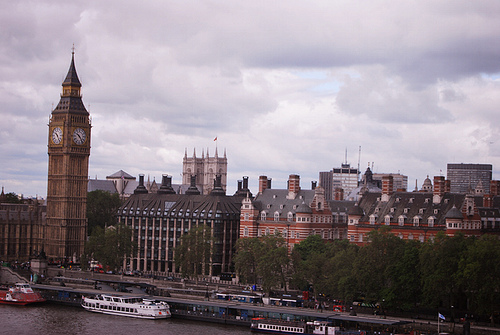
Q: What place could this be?
A: It is a city.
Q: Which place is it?
A: It is a city.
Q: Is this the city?
A: Yes, it is the city.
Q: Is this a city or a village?
A: It is a city.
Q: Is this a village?
A: No, it is a city.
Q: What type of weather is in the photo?
A: It is cloudy.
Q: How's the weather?
A: It is cloudy.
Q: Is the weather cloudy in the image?
A: Yes, it is cloudy.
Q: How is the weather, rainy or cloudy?
A: It is cloudy.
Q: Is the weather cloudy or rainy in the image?
A: It is cloudy.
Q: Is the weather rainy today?
A: No, it is cloudy.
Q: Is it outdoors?
A: Yes, it is outdoors.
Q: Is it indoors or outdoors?
A: It is outdoors.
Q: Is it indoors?
A: No, it is outdoors.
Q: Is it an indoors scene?
A: No, it is outdoors.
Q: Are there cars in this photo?
A: No, there are no cars.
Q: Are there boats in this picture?
A: Yes, there is a boat.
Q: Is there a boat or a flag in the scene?
A: Yes, there is a boat.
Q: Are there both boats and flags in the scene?
A: Yes, there are both a boat and a flag.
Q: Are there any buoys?
A: No, there are no buoys.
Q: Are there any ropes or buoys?
A: No, there are no buoys or ropes.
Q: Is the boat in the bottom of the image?
A: Yes, the boat is in the bottom of the image.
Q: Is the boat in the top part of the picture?
A: No, the boat is in the bottom of the image.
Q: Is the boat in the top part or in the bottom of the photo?
A: The boat is in the bottom of the image.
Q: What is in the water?
A: The boat is in the water.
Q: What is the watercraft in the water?
A: The watercraft is a boat.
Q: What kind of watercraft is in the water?
A: The watercraft is a boat.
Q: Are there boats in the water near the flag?
A: Yes, there is a boat in the water.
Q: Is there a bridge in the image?
A: Yes, there is a bridge.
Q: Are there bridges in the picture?
A: Yes, there is a bridge.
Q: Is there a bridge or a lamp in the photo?
A: Yes, there is a bridge.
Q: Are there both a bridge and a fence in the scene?
A: No, there is a bridge but no fences.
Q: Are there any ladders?
A: No, there are no ladders.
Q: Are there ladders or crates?
A: No, there are no ladders or crates.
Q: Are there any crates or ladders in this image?
A: No, there are no ladders or crates.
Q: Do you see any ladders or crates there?
A: No, there are no ladders or crates.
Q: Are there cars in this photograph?
A: No, there are no cars.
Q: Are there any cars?
A: No, there are no cars.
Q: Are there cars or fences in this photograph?
A: No, there are no cars or fences.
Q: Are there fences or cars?
A: No, there are no cars or fences.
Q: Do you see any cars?
A: No, there are no cars.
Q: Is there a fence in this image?
A: No, there are no fences.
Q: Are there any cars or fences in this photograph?
A: No, there are no fences or cars.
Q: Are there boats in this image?
A: Yes, there is a boat.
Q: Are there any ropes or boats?
A: Yes, there is a boat.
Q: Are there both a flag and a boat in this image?
A: Yes, there are both a boat and a flag.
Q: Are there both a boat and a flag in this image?
A: Yes, there are both a boat and a flag.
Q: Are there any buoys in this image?
A: No, there are no buoys.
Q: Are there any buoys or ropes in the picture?
A: No, there are no buoys or ropes.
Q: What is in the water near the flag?
A: The boat is in the water.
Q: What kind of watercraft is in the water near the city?
A: The watercraft is a boat.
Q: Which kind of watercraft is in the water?
A: The watercraft is a boat.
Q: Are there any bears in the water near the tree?
A: No, there is a boat in the water.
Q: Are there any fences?
A: No, there are no fences.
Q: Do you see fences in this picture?
A: No, there are no fences.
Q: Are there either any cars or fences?
A: No, there are no fences or cars.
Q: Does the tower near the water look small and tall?
A: No, the tower is tall but large.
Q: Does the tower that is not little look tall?
A: Yes, the tower is tall.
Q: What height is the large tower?
A: The tower is tall.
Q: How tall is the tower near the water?
A: The tower is tall.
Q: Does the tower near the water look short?
A: No, the tower is tall.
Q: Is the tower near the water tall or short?
A: The tower is tall.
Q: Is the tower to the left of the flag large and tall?
A: Yes, the tower is large and tall.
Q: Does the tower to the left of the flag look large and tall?
A: Yes, the tower is large and tall.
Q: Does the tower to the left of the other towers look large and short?
A: No, the tower is large but tall.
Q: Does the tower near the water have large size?
A: Yes, the tower is large.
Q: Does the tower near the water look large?
A: Yes, the tower is large.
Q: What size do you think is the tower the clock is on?
A: The tower is large.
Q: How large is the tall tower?
A: The tower is large.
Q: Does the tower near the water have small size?
A: No, the tower is large.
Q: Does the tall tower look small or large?
A: The tower is large.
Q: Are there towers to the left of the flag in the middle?
A: Yes, there is a tower to the left of the flag.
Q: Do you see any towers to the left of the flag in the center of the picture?
A: Yes, there is a tower to the left of the flag.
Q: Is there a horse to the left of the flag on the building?
A: No, there is a tower to the left of the flag.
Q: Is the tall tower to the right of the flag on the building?
A: No, the tower is to the left of the flag.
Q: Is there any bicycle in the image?
A: No, there are no bicycles.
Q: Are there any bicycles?
A: No, there are no bicycles.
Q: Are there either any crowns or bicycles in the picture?
A: No, there are no bicycles or crowns.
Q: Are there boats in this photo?
A: Yes, there is a boat.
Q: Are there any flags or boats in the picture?
A: Yes, there is a boat.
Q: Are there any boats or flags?
A: Yes, there is a boat.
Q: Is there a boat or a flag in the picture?
A: Yes, there is a boat.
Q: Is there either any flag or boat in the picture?
A: Yes, there is a boat.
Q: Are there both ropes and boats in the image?
A: No, there is a boat but no ropes.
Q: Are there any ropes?
A: No, there are no ropes.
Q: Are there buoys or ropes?
A: No, there are no ropes or buoys.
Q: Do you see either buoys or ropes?
A: No, there are no ropes or buoys.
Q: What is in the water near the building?
A: The boat is in the water.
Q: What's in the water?
A: The boat is in the water.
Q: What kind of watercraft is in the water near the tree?
A: The watercraft is a boat.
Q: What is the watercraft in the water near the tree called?
A: The watercraft is a boat.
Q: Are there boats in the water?
A: Yes, there is a boat in the water.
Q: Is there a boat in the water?
A: Yes, there is a boat in the water.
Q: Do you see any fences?
A: No, there are no fences.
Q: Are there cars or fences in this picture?
A: No, there are no fences or cars.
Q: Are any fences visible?
A: No, there are no fences.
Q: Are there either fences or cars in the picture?
A: No, there are no fences or cars.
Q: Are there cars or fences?
A: No, there are no fences or cars.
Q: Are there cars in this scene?
A: No, there are no cars.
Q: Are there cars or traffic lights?
A: No, there are no cars or traffic lights.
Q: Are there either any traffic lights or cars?
A: No, there are no cars or traffic lights.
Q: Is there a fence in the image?
A: No, there are no fences.